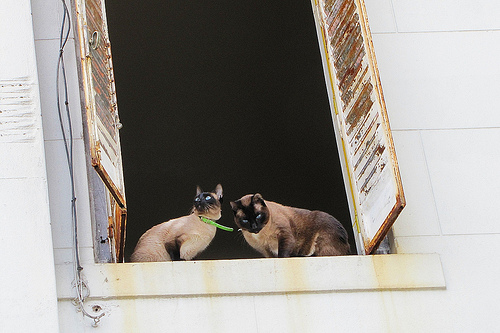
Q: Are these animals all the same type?
A: Yes, all the animals are cats.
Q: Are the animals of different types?
A: No, all the animals are cats.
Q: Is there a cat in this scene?
A: Yes, there are cats.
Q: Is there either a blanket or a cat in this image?
A: Yes, there are cats.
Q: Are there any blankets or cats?
A: Yes, there are cats.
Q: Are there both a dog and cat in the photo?
A: No, there are cats but no dogs.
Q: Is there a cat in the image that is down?
A: Yes, there are cats that are down.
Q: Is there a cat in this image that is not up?
A: Yes, there are cats that are down.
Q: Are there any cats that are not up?
A: Yes, there are cats that are down.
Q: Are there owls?
A: No, there are no owls.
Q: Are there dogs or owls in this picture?
A: No, there are no owls or dogs.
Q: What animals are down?
A: The animals are cats.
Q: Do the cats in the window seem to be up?
A: No, the cats are down.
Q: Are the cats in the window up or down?
A: The cats are down.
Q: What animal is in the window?
A: The cats are in the window.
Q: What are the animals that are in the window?
A: The animals are cats.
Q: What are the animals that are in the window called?
A: The animals are cats.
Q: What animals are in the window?
A: The animals are cats.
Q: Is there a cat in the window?
A: Yes, there are cats in the window.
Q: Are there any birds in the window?
A: No, there are cats in the window.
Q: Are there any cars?
A: No, there are no cars.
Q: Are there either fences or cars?
A: No, there are no cars or fences.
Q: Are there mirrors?
A: No, there are no mirrors.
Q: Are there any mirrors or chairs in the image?
A: No, there are no mirrors or chairs.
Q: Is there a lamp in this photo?
A: No, there are no lamps.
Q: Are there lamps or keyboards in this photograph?
A: No, there are no lamps or keyboards.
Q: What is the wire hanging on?
A: The wire is hanging on the wall.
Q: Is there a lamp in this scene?
A: No, there are no lamps.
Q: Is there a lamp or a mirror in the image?
A: No, there are no lamps or mirrors.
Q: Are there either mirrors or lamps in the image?
A: No, there are no lamps or mirrors.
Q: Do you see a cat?
A: Yes, there is a cat.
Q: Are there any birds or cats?
A: Yes, there is a cat.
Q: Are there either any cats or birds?
A: Yes, there is a cat.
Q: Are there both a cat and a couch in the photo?
A: No, there is a cat but no couches.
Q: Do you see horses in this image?
A: No, there are no horses.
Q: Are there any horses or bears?
A: No, there are no horses or bears.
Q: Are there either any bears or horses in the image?
A: No, there are no horses or bears.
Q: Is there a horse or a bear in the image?
A: No, there are no horses or bears.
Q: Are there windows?
A: Yes, there is a window.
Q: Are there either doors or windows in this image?
A: Yes, there is a window.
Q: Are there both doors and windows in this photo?
A: No, there is a window but no doors.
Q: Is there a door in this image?
A: No, there are no doors.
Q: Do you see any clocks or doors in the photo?
A: No, there are no doors or clocks.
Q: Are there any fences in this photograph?
A: No, there are no fences.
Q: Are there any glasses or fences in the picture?
A: No, there are no fences or glasses.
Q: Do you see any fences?
A: No, there are no fences.